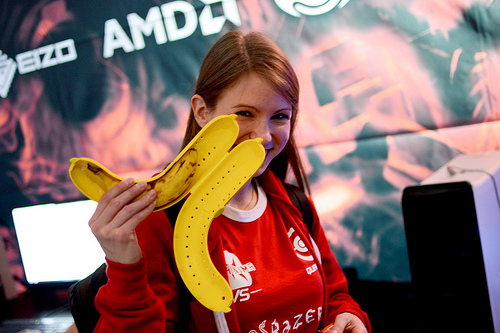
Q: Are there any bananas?
A: Yes, there is a banana.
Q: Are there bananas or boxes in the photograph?
A: Yes, there is a banana.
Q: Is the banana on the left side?
A: Yes, the banana is on the left of the image.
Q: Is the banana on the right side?
A: No, the banana is on the left of the image.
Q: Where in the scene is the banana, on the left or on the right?
A: The banana is on the left of the image.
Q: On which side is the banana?
A: The banana is on the left of the image.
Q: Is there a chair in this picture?
A: No, there are no chairs.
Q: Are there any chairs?
A: No, there are no chairs.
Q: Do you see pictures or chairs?
A: No, there are no chairs or pictures.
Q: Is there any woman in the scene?
A: Yes, there is a woman.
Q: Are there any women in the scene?
A: Yes, there is a woman.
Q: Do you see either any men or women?
A: Yes, there is a woman.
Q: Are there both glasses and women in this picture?
A: No, there is a woman but no glasses.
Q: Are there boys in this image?
A: No, there are no boys.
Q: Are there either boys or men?
A: No, there are no boys or men.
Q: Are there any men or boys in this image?
A: No, there are no boys or men.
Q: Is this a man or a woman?
A: This is a woman.